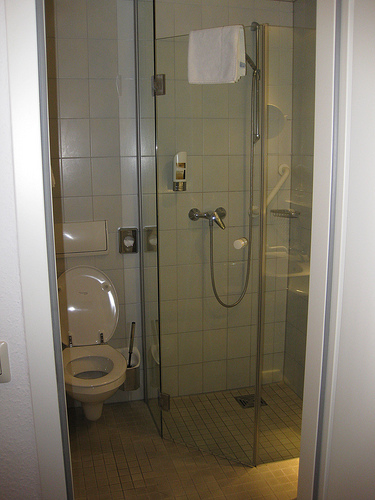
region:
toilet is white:
[55, 257, 132, 438]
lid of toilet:
[52, 261, 123, 345]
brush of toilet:
[114, 319, 147, 396]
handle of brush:
[121, 319, 141, 371]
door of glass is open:
[147, 11, 310, 470]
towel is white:
[180, 17, 249, 92]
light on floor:
[250, 457, 299, 498]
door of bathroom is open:
[25, 5, 340, 498]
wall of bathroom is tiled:
[49, 1, 150, 408]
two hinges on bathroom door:
[141, 71, 180, 421]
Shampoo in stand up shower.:
[170, 144, 195, 203]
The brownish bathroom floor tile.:
[103, 448, 197, 490]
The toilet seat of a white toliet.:
[78, 378, 114, 390]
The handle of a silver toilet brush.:
[125, 318, 140, 360]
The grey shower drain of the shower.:
[230, 387, 268, 415]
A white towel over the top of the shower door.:
[179, 24, 254, 90]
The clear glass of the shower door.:
[163, 307, 257, 401]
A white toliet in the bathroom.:
[58, 263, 127, 429]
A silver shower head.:
[207, 208, 228, 238]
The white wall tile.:
[56, 55, 116, 151]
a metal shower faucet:
[185, 206, 228, 227]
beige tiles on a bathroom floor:
[69, 430, 165, 498]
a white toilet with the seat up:
[58, 266, 133, 427]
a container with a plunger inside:
[117, 325, 148, 394]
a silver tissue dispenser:
[116, 222, 142, 262]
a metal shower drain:
[233, 392, 267, 410]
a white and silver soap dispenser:
[170, 151, 187, 197]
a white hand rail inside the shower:
[237, 158, 297, 224]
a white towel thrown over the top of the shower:
[176, 19, 247, 87]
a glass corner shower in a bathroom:
[137, 24, 302, 468]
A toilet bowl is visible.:
[26, 249, 119, 387]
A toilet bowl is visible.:
[39, 267, 138, 448]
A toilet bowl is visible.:
[50, 242, 156, 395]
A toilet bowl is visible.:
[11, 177, 162, 417]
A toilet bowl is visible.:
[46, 210, 216, 474]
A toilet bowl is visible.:
[39, 246, 181, 493]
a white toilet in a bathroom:
[65, 265, 122, 428]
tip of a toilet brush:
[122, 321, 144, 368]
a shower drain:
[232, 381, 266, 414]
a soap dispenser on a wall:
[169, 144, 195, 204]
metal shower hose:
[200, 88, 262, 202]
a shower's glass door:
[155, 125, 258, 461]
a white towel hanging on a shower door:
[187, 26, 252, 89]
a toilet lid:
[58, 265, 123, 348]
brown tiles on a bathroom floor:
[105, 444, 233, 492]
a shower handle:
[185, 199, 233, 234]